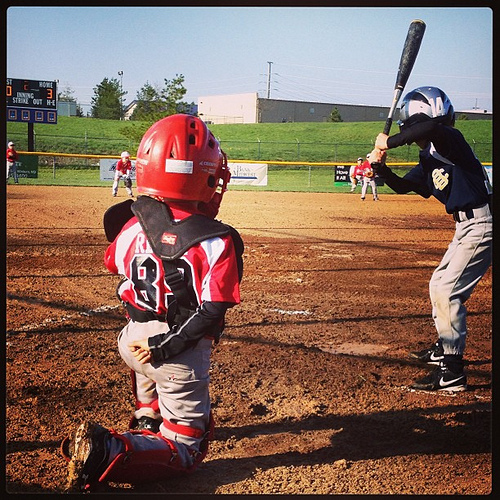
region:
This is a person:
[391, 58, 498, 403]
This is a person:
[362, 152, 382, 217]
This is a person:
[346, 145, 363, 202]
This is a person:
[110, 141, 145, 201]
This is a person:
[5, 131, 26, 191]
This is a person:
[79, 99, 280, 496]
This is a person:
[102, 132, 157, 214]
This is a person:
[362, 139, 397, 202]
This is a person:
[336, 138, 366, 198]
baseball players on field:
[40, 8, 485, 486]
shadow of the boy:
[255, 419, 472, 474]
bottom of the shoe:
[46, 433, 101, 478]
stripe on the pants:
[158, 415, 202, 443]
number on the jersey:
[113, 246, 165, 303]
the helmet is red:
[131, 122, 217, 199]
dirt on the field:
[242, 371, 334, 392]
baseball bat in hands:
[394, 10, 414, 189]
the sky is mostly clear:
[272, 22, 335, 56]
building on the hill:
[195, 83, 290, 124]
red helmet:
[110, 103, 240, 227]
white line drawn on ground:
[255, 297, 329, 329]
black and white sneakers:
[406, 333, 468, 402]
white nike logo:
[434, 373, 467, 392]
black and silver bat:
[363, 14, 432, 184]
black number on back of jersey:
[122, 248, 198, 327]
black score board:
[7, 70, 67, 150]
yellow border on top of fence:
[6, 140, 491, 198]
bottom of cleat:
[47, 419, 109, 494]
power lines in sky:
[191, 53, 498, 107]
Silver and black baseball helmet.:
[400, 80, 465, 140]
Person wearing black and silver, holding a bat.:
[365, 10, 495, 200]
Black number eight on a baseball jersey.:
[115, 240, 170, 320]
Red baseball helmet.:
[130, 95, 225, 220]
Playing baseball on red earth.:
[360, 5, 495, 405]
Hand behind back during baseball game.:
[297, 163, 298, 173]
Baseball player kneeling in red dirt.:
[155, 395, 230, 485]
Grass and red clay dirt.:
[205, 120, 427, 378]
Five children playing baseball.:
[105, 5, 490, 490]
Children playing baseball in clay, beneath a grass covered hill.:
[62, 54, 486, 497]